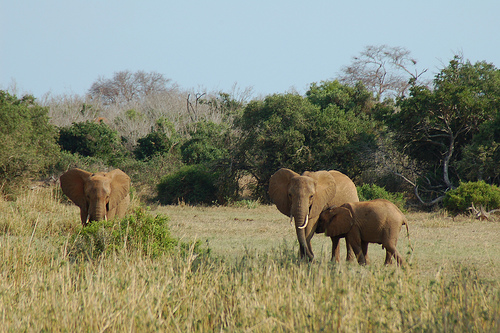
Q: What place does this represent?
A: It represents the field.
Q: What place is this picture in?
A: It is at the field.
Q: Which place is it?
A: It is a field.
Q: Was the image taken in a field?
A: Yes, it was taken in a field.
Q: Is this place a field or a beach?
A: It is a field.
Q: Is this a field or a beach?
A: It is a field.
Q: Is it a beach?
A: No, it is a field.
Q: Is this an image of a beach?
A: No, the picture is showing a field.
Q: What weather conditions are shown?
A: It is clear.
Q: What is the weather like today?
A: It is clear.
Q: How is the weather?
A: It is clear.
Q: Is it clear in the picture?
A: Yes, it is clear.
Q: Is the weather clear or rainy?
A: It is clear.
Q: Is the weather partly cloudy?
A: No, it is clear.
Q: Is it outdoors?
A: Yes, it is outdoors.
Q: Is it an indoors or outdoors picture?
A: It is outdoors.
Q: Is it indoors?
A: No, it is outdoors.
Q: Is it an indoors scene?
A: No, it is outdoors.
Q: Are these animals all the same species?
A: Yes, all the animals are elephants.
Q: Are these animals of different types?
A: No, all the animals are elephants.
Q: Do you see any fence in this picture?
A: No, there are no fences.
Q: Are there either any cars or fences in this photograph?
A: No, there are no fences or cars.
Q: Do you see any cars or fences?
A: No, there are no fences or cars.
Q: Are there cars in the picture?
A: No, there are no cars.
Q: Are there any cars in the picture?
A: No, there are no cars.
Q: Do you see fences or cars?
A: No, there are no cars or fences.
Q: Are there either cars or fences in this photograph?
A: No, there are no cars or fences.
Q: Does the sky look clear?
A: Yes, the sky is clear.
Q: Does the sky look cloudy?
A: No, the sky is clear.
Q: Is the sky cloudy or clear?
A: The sky is clear.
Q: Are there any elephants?
A: Yes, there is an elephant.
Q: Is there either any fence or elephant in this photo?
A: Yes, there is an elephant.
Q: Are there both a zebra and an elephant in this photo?
A: No, there is an elephant but no zebras.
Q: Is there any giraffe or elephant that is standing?
A: Yes, the elephant is standing.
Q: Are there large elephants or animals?
A: Yes, there is a large elephant.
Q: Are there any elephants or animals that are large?
A: Yes, the elephant is large.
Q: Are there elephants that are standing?
A: Yes, there is an elephant that is standing.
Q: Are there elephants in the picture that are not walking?
A: Yes, there is an elephant that is standing.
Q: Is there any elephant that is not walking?
A: Yes, there is an elephant that is standing.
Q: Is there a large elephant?
A: Yes, there is a large elephant.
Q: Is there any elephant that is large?
A: Yes, there is an elephant that is large.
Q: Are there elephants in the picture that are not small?
A: Yes, there is a large elephant.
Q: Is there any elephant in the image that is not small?
A: Yes, there is a large elephant.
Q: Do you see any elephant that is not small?
A: Yes, there is a large elephant.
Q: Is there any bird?
A: No, there are no birds.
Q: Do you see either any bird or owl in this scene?
A: No, there are no birds or owls.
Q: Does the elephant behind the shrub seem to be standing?
A: Yes, the elephant is standing.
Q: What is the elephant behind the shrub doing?
A: The elephant is standing.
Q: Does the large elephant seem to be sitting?
A: No, the elephant is standing.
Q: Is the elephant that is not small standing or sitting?
A: The elephant is standing.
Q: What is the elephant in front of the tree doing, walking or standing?
A: The elephant is standing.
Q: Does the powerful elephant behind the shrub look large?
A: Yes, the elephant is large.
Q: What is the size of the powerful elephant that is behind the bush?
A: The elephant is large.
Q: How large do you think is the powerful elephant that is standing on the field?
A: The elephant is large.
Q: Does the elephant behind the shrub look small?
A: No, the elephant is large.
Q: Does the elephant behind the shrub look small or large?
A: The elephant is large.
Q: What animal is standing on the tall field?
A: The animal is an elephant.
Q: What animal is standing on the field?
A: The animal is an elephant.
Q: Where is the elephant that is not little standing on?
A: The elephant is standing on the field.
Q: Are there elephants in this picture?
A: Yes, there is an elephant.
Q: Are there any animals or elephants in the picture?
A: Yes, there is an elephant.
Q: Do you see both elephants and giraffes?
A: No, there is an elephant but no giraffes.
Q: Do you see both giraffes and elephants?
A: No, there is an elephant but no giraffes.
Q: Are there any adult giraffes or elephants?
A: Yes, there is an adult elephant.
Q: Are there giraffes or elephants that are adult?
A: Yes, the elephant is adult.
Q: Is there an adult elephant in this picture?
A: Yes, there is an adult elephant.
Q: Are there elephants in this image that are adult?
A: Yes, there is an elephant that is adult.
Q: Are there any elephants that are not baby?
A: Yes, there is a adult elephant.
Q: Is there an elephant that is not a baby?
A: Yes, there is a adult elephant.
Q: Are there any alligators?
A: No, there are no alligators.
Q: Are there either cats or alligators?
A: No, there are no alligators or cats.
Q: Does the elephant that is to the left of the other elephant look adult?
A: Yes, the elephant is adult.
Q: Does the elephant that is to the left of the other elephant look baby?
A: No, the elephant is adult.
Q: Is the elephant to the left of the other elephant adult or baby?
A: The elephant is adult.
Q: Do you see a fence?
A: No, there are no fences.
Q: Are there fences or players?
A: No, there are no fences or players.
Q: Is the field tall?
A: Yes, the field is tall.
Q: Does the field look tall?
A: Yes, the field is tall.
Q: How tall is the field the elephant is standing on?
A: The field is tall.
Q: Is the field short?
A: No, the field is tall.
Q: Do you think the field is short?
A: No, the field is tall.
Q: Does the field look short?
A: No, the field is tall.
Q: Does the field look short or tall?
A: The field is tall.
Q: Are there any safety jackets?
A: No, there are no safety jackets.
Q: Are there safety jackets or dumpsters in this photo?
A: No, there are no safety jackets or dumpsters.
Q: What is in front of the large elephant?
A: The bush is in front of the elephant.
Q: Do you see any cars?
A: No, there are no cars.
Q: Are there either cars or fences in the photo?
A: No, there are no cars or fences.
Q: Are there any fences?
A: No, there are no fences.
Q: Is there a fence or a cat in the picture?
A: No, there are no fences or cats.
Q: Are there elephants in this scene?
A: Yes, there is an elephant.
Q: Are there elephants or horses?
A: Yes, there is an elephant.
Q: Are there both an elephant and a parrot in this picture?
A: No, there is an elephant but no parrots.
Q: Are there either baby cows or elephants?
A: Yes, there is a baby elephant.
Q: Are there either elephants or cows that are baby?
A: Yes, the elephant is a baby.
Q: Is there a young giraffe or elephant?
A: Yes, there is a young elephant.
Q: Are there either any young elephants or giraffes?
A: Yes, there is a young elephant.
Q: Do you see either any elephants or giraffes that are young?
A: Yes, the elephant is young.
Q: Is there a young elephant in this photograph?
A: Yes, there is a young elephant.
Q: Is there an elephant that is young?
A: Yes, there is an elephant that is young.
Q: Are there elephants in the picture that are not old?
A: Yes, there is an young elephant.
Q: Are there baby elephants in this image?
A: Yes, there is a baby elephant.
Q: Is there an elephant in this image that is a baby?
A: Yes, there is an elephant that is a baby.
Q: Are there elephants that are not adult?
A: Yes, there is an baby elephant.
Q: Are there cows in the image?
A: No, there are no cows.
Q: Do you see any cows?
A: No, there are no cows.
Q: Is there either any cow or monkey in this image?
A: No, there are no cows or monkeys.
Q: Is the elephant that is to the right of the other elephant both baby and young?
A: Yes, the elephant is a baby and young.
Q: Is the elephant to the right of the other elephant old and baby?
A: No, the elephant is a baby but young.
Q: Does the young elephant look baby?
A: Yes, the elephant is a baby.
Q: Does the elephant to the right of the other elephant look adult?
A: No, the elephant is a baby.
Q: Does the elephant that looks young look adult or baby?
A: The elephant is a baby.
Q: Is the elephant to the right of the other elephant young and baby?
A: Yes, the elephant is young and baby.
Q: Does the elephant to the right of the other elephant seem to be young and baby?
A: Yes, the elephant is young and baby.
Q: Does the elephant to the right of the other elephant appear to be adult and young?
A: No, the elephant is young but baby.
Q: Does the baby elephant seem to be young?
A: Yes, the elephant is young.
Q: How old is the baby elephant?
A: The elephant is young.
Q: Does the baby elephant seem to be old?
A: No, the elephant is young.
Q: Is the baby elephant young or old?
A: The elephant is young.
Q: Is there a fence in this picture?
A: No, there are no fences.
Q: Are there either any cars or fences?
A: No, there are no fences or cars.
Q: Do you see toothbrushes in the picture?
A: No, there are no toothbrushes.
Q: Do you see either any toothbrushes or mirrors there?
A: No, there are no toothbrushes or mirrors.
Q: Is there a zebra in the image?
A: No, there are no zebras.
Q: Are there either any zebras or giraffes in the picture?
A: No, there are no zebras or giraffes.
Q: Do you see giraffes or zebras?
A: No, there are no zebras or giraffes.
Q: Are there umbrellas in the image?
A: No, there are no umbrellas.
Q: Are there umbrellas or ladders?
A: No, there are no umbrellas or ladders.